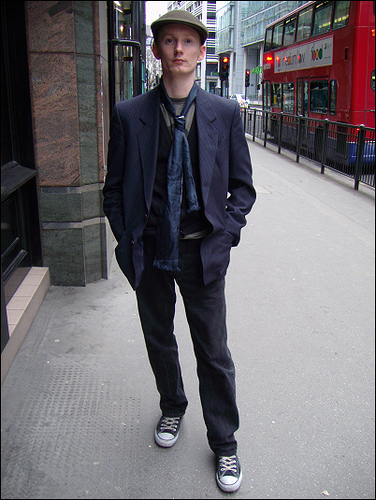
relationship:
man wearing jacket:
[101, 8, 260, 496] [102, 83, 255, 289]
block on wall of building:
[35, 51, 101, 187] [1, 2, 147, 384]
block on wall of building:
[29, 2, 98, 52] [1, 2, 147, 384]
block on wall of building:
[38, 192, 104, 215] [1, 2, 147, 384]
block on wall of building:
[41, 222, 103, 284] [1, 2, 147, 384]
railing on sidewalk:
[239, 106, 375, 194] [252, 163, 372, 462]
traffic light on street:
[244, 69, 249, 86] [241, 112, 374, 187]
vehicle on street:
[227, 92, 251, 109] [228, 103, 375, 186]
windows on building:
[214, 10, 232, 28] [211, 2, 309, 105]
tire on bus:
[270, 118, 280, 141] [260, 1, 374, 164]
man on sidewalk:
[95, 8, 265, 496] [5, 127, 374, 492]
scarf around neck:
[153, 82, 206, 263] [159, 75, 196, 99]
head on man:
[116, 0, 212, 105] [95, 8, 265, 496]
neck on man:
[157, 67, 196, 102] [95, 8, 265, 496]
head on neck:
[116, 0, 212, 105] [157, 67, 196, 102]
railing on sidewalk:
[202, 73, 372, 189] [5, 127, 374, 492]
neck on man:
[161, 73, 195, 103] [101, 8, 260, 496]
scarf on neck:
[153, 82, 206, 270] [161, 73, 195, 103]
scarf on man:
[153, 82, 206, 270] [101, 8, 260, 496]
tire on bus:
[313, 129, 325, 161] [259, 1, 362, 163]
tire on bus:
[270, 118, 280, 141] [259, 1, 362, 163]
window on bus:
[310, 79, 330, 113] [260, 1, 374, 164]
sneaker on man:
[211, 452, 242, 493] [95, 8, 265, 496]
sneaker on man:
[152, 412, 183, 447] [95, 8, 265, 496]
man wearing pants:
[101, 8, 260, 496] [128, 234, 239, 456]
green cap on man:
[147, 10, 208, 42] [95, 8, 265, 496]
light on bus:
[265, 52, 271, 61] [258, 0, 367, 141]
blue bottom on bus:
[277, 125, 372, 189] [261, 3, 371, 175]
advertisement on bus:
[269, 46, 331, 70] [260, 1, 374, 164]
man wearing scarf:
[95, 8, 265, 496] [153, 77, 208, 275]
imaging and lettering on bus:
[283, 38, 345, 100] [293, 86, 364, 202]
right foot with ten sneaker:
[149, 415, 189, 475] [152, 412, 183, 447]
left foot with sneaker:
[217, 453, 261, 500] [213, 452, 242, 493]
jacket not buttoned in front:
[125, 96, 233, 271] [138, 116, 234, 282]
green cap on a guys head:
[147, 10, 208, 42] [153, 47, 194, 72]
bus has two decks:
[260, 1, 374, 164] [233, 38, 310, 107]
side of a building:
[24, 1, 116, 288] [1, 2, 147, 384]